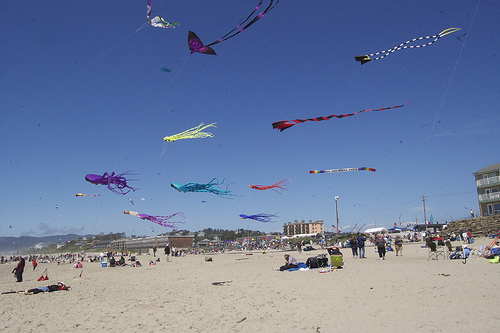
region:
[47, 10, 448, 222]
A variety of multi-colored kites in the dark blue sky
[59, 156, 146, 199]
Dark purple kite shaped like a squid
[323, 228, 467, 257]
Beach goers walking around on the sand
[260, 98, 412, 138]
Black and red long kite in the sky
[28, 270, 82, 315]
Person laying down in the sand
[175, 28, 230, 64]
Butterfly shaped purple kite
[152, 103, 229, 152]
Bright yellow kite in the sky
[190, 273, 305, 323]
Light tan colored sand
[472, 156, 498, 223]
Tall blue beach house near the sand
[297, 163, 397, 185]
Banner in the sky with writing on a white background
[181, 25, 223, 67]
the kite is purple and black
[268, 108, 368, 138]
the kite is red and black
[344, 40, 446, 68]
the kite is black yellow and white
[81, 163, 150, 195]
the kite is purple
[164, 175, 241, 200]
the kite is torquious and black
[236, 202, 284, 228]
the kite is blue in color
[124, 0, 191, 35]
the kite is white purple and green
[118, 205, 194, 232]
the kite is red white and purple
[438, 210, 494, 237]
the stone wall is brown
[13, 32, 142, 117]
the sky is blue in color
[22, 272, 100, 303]
person is laying in the sand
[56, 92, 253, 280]
kites are being flown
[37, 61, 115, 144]
the sky is clear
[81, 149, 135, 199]
a purple kite in the sky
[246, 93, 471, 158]
red and blue kite in the air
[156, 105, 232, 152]
yellow kite in the air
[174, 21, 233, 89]
purple butterfly kite in sky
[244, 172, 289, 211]
red kite in the sky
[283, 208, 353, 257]
building in the background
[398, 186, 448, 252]
electrical pole in background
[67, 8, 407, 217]
Lots of kites in the sky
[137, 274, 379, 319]
Sand on the beach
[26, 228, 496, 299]
People relaxing in the beach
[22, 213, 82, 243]
Distant clouds in the sky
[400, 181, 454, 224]
Distant electrical power lines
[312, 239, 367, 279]
Relaxing in a beach chair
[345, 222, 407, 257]
Some are lfying kites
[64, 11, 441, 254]
Many colors for the kites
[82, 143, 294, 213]
Squid looking kites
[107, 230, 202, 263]
A building in the distance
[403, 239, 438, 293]
part of the beach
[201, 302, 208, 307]
section of the sand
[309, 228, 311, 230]
part of a building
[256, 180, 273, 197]
a red kite in air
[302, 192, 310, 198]
part of the sky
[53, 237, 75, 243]
part of a mountain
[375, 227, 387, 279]
body of a man